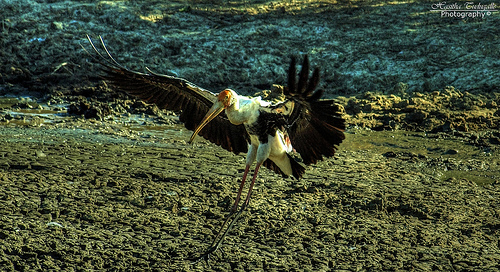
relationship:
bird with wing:
[77, 41, 345, 268] [269, 55, 341, 120]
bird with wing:
[77, 41, 345, 268] [61, 32, 244, 144]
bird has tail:
[77, 41, 345, 268] [279, 44, 354, 169]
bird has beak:
[77, 41, 345, 268] [188, 100, 224, 145]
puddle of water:
[422, 157, 499, 196] [359, 118, 468, 164]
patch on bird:
[230, 89, 267, 125] [84, 42, 345, 225]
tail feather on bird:
[306, 65, 321, 102] [77, 41, 345, 268]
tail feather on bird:
[310, 79, 333, 103] [77, 41, 345, 268]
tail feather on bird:
[282, 50, 296, 96] [77, 41, 345, 268]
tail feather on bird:
[296, 53, 308, 101] [77, 41, 345, 268]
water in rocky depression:
[332, 122, 497, 164] [335, 80, 497, 190]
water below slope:
[30, 89, 492, 166] [1, 1, 495, 97]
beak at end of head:
[188, 100, 224, 145] [186, 86, 232, 144]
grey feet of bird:
[181, 244, 227, 267] [77, 41, 345, 268]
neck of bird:
[232, 101, 259, 125] [81, 32, 347, 249]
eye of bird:
[224, 90, 232, 102] [87, 27, 353, 261]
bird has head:
[77, 41, 345, 268] [219, 87, 239, 113]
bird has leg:
[130, 67, 360, 178] [190, 160, 261, 258]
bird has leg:
[130, 67, 360, 178] [181, 158, 249, 261]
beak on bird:
[186, 100, 224, 150] [72, 32, 405, 262]